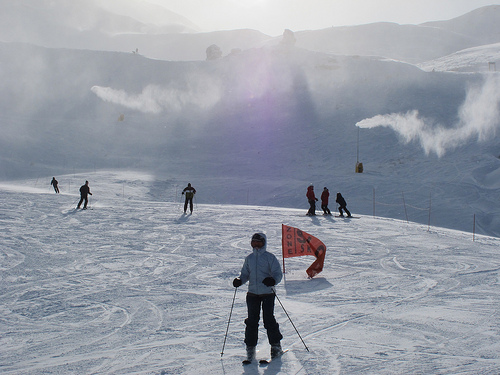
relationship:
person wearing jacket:
[236, 227, 284, 362] [237, 233, 283, 294]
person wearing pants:
[236, 227, 284, 362] [246, 296, 282, 346]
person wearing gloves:
[236, 227, 284, 362] [229, 275, 277, 288]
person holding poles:
[236, 227, 284, 362] [214, 288, 320, 360]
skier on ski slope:
[305, 185, 318, 216] [0, 190, 499, 373]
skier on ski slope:
[319, 185, 330, 215] [0, 190, 499, 373]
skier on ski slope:
[335, 194, 355, 217] [0, 190, 499, 373]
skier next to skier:
[305, 185, 318, 216] [319, 185, 330, 215]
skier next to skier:
[319, 185, 330, 215] [335, 194, 355, 217]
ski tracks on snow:
[70, 250, 180, 310] [393, 262, 440, 318]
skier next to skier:
[302, 182, 318, 215] [320, 187, 330, 215]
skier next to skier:
[320, 187, 330, 215] [333, 191, 352, 218]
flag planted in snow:
[280, 221, 326, 278] [2, 180, 495, 374]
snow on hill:
[2, 180, 495, 374] [0, 178, 498, 373]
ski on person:
[258, 345, 288, 367] [236, 227, 284, 362]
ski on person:
[239, 341, 256, 363] [236, 227, 284, 362]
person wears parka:
[236, 227, 284, 362] [233, 245, 282, 296]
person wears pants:
[236, 227, 284, 362] [247, 295, 281, 351]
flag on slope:
[282, 223, 327, 278] [8, 190, 498, 373]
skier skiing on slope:
[75, 176, 92, 211] [10, 211, 223, 365]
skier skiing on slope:
[184, 183, 194, 212] [10, 211, 223, 365]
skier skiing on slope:
[49, 176, 61, 196] [10, 211, 223, 365]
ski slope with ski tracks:
[0, 190, 499, 373] [38, 228, 151, 340]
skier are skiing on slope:
[305, 185, 318, 216] [10, 211, 223, 365]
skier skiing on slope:
[77, 180, 93, 210] [10, 211, 223, 365]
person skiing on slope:
[236, 227, 284, 362] [10, 211, 223, 365]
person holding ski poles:
[236, 227, 284, 362] [208, 286, 242, 366]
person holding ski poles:
[236, 227, 284, 362] [273, 290, 311, 355]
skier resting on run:
[305, 185, 318, 216] [0, 212, 498, 368]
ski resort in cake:
[22, 46, 477, 280] [206, 225, 298, 365]